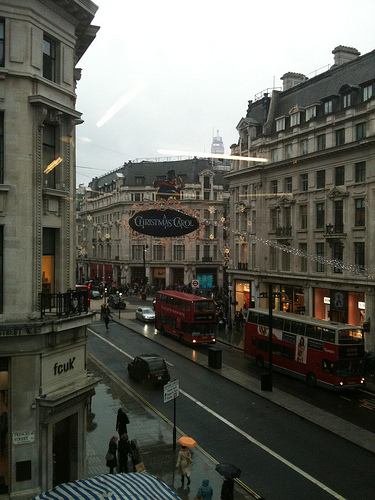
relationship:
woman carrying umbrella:
[178, 446, 194, 488] [178, 437, 195, 447]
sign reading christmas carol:
[129, 208, 200, 237] [133, 217, 195, 230]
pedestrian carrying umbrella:
[178, 446, 194, 488] [178, 437, 195, 447]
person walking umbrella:
[178, 446, 194, 488] [178, 437, 195, 447]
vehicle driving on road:
[128, 353, 168, 386] [76, 273, 371, 500]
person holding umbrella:
[178, 446, 194, 488] [178, 437, 195, 447]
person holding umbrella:
[217, 466, 236, 500] [217, 463, 238, 477]